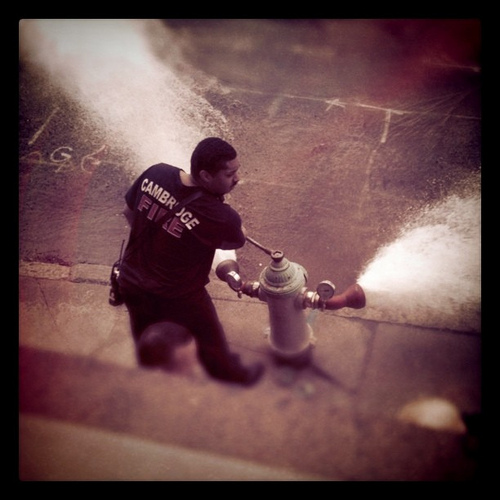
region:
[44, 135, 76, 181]
Letter G in chalk on ground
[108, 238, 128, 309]
A walkie talkie on man's jeans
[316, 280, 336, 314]
An water gauge is on the fire hydrant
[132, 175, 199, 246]
Back of man shirt says Cambridge Fire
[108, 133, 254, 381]
A fireman has black shirt and pants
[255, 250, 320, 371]
a red and white fire hydrant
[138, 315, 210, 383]
head of another man walk by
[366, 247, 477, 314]
water spraying on street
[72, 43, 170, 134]
water is spraying on left side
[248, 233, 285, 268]
Using wrench on fire hydrant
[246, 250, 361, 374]
a fire hydrant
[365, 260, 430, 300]
water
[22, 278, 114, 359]
the sidewalk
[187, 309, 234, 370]
the man is wearing pants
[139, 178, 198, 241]
writing on the shirt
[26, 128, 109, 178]
writing on the street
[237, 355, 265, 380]
man is wearing shoes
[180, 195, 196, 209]
strap on the back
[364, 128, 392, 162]
drawing on the sidewalk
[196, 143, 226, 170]
the man has short hair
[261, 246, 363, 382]
a fire hydrant on the street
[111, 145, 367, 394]
a fireman on the street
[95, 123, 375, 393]
a fire man flushing a hydrant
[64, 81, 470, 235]
a black top street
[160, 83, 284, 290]
water from the hydrant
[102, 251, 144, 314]
a radio on his side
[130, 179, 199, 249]
writing on a t shirt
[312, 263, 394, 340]
a pressure gage on the pip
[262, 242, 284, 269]
a bolt on a fire hydrant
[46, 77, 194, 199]
writing on the road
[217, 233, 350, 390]
fire hydrant with water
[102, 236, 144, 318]
walke-talkie on mans hip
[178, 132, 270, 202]
man looking to the right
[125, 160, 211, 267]
t-shirt with fire department name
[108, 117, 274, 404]
man opening a fire hydrant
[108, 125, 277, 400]
man standing on sidewalk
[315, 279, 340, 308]
pressure guage on right side of hydrant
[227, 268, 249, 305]
pressure guage on left side of hydrant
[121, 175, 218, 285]
strap over mans shoulder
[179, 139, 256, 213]
man with short curly hair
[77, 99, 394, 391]
Fireman testing fire hydrant.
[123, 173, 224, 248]
Man's shirt says CAMBRIDGE FIRE.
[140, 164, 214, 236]
The word CAMBRIDGE in white letters.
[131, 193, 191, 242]
The word FIRE in red letters.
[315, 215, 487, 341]
Water gushing from right side of hydrant.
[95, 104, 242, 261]
Water gushing from left side of hydrant.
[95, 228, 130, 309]
Radio on fireman's belt.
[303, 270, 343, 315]
Gauge on right side of hydrant.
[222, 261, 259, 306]
Gauge on left side of hydrant.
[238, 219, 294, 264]
Tool to open hydrant.